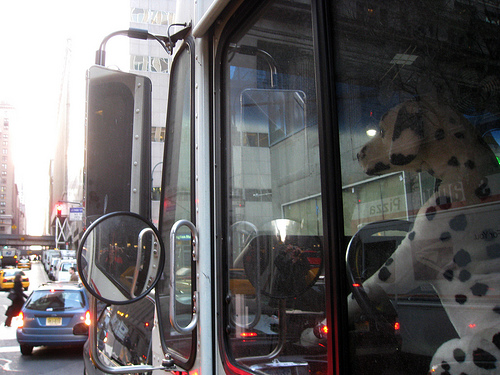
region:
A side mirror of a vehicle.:
[74, 208, 166, 305]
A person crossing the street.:
[3, 266, 29, 328]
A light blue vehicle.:
[11, 278, 94, 357]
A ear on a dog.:
[386, 93, 428, 171]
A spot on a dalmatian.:
[469, 345, 499, 371]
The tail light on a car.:
[16, 308, 26, 330]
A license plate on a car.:
[43, 313, 65, 328]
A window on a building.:
[148, 55, 168, 71]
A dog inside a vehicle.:
[298, 93, 499, 374]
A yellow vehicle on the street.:
[1, 263, 30, 291]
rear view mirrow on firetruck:
[86, 207, 164, 306]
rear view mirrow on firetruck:
[83, 59, 158, 199]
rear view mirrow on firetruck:
[83, 307, 188, 372]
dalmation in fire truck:
[379, 115, 484, 261]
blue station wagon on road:
[12, 272, 97, 348]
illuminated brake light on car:
[11, 303, 26, 332]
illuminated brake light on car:
[77, 309, 96, 334]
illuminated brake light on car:
[45, 287, 59, 298]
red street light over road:
[59, 207, 82, 223]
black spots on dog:
[414, 258, 470, 318]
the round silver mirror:
[75, 214, 155, 301]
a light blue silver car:
[16, 285, 91, 349]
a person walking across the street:
[2, 268, 34, 333]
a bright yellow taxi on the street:
[0, 265, 30, 289]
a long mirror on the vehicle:
[80, 65, 155, 315]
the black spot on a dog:
[377, 265, 389, 282]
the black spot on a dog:
[455, 248, 472, 266]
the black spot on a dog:
[470, 279, 489, 297]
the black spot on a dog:
[450, 344, 467, 363]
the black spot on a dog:
[470, 343, 496, 372]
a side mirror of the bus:
[75, 209, 167, 306]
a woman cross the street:
[3, 267, 28, 333]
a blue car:
[13, 283, 93, 358]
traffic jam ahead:
[3, 246, 76, 282]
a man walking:
[66, 265, 79, 280]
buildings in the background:
[3, 77, 70, 228]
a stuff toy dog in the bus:
[298, 95, 496, 373]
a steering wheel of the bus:
[343, 212, 411, 347]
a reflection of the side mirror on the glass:
[241, 217, 323, 303]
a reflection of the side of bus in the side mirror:
[77, 210, 162, 305]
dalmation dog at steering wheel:
[343, 85, 499, 315]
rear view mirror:
[60, 178, 240, 350]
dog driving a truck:
[302, 70, 489, 373]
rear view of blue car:
[5, 278, 101, 367]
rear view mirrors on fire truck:
[73, 15, 210, 367]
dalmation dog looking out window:
[256, 34, 493, 207]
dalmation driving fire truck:
[337, 90, 499, 362]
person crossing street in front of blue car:
[2, 262, 89, 349]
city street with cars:
[1, 170, 91, 365]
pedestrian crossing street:
[5, 256, 94, 351]